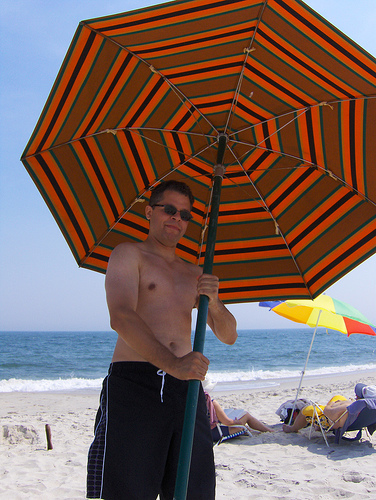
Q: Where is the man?
A: At the beach.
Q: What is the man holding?
A: An umbrella.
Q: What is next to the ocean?
A: The beach.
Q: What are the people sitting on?
A: Lounge chairs.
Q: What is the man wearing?
A: Swim trunks.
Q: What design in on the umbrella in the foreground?
A: Stripes.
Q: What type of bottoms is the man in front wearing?
A: Swim trunks.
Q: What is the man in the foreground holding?
A: Umbrella.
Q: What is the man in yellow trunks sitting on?
A: Chair.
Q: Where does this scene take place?
A: Beach.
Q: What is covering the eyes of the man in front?
A: Sunglasses.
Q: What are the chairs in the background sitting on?
A: Sand.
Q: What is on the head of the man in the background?
A: Hat.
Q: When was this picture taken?
A: Daytime.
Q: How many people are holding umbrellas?
A: One.